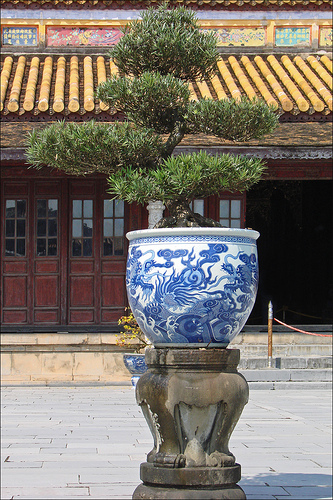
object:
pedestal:
[132, 346, 252, 499]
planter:
[123, 220, 260, 351]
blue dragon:
[126, 239, 258, 341]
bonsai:
[20, 2, 291, 227]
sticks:
[166, 116, 184, 158]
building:
[0, 3, 333, 334]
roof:
[3, 3, 332, 118]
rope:
[273, 315, 333, 340]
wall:
[1, 352, 140, 386]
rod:
[52, 52, 69, 113]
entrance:
[244, 179, 332, 327]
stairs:
[230, 324, 331, 385]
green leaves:
[146, 32, 156, 54]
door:
[3, 173, 73, 337]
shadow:
[238, 467, 332, 499]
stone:
[232, 321, 333, 349]